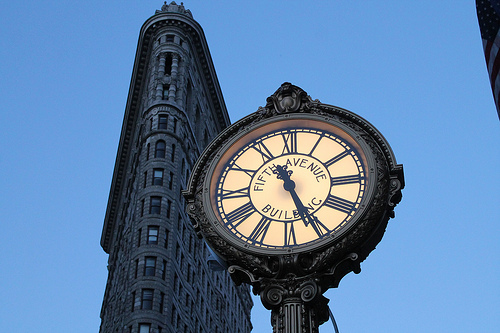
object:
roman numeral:
[284, 222, 297, 247]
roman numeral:
[280, 130, 300, 155]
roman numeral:
[249, 140, 275, 162]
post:
[269, 301, 317, 333]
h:
[267, 164, 281, 173]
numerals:
[224, 199, 259, 228]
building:
[96, 0, 252, 333]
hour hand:
[279, 169, 306, 227]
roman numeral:
[319, 190, 353, 215]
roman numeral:
[331, 174, 359, 187]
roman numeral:
[215, 188, 249, 199]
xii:
[281, 132, 299, 155]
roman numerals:
[308, 130, 326, 156]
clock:
[207, 127, 364, 251]